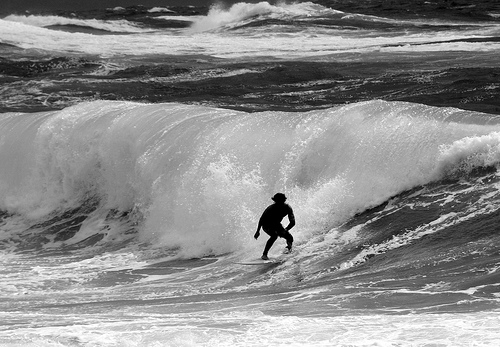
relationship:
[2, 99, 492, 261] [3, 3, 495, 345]
waters in ocean water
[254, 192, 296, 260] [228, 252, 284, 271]
man standing on board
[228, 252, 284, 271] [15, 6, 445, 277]
board riding waves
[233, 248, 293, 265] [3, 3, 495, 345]
board in ocean water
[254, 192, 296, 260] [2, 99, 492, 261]
man with waters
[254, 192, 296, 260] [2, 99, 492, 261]
man on waters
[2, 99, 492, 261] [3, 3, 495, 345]
waters on ocean water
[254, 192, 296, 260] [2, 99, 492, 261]
man riding waters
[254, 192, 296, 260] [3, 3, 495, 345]
man riding ocean water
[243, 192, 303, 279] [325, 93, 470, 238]
man surfing wave